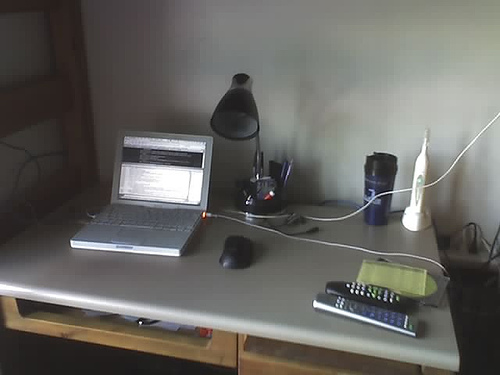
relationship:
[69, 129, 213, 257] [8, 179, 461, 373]
computer on table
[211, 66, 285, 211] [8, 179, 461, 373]
lamp on table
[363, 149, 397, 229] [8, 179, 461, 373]
cup on table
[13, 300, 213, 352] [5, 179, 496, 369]
cubbie under desk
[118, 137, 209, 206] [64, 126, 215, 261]
screen on laptop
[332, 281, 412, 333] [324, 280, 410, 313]
buttons on remote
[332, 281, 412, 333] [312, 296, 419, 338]
buttons on remote control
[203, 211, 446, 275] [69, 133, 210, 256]
wire on computer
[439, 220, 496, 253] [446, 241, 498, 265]
wires on strips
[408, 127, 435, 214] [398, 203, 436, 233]
electric brush on base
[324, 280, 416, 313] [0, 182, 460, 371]
remote on table top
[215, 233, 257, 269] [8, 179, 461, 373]
mouse on table